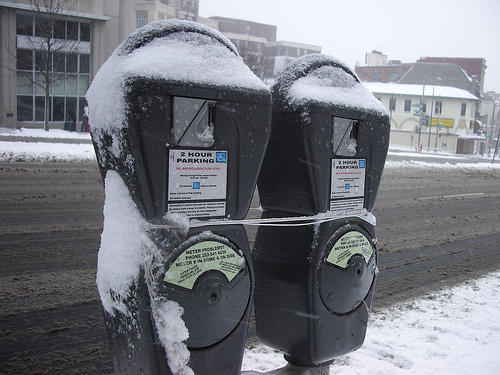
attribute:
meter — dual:
[82, 17, 274, 374]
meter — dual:
[252, 51, 392, 373]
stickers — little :
[163, 145, 371, 219]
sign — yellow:
[424, 114, 454, 128]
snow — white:
[401, 317, 488, 372]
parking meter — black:
[82, 15, 273, 373]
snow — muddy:
[398, 311, 491, 368]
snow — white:
[122, 37, 254, 90]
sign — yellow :
[429, 118, 456, 128]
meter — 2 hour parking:
[71, 10, 393, 374]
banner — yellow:
[411, 99, 481, 146]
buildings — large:
[2, 0, 496, 150]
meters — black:
[78, 9, 401, 374]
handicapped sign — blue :
[209, 149, 234, 171]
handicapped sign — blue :
[348, 149, 368, 176]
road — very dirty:
[1, 156, 499, 369]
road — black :
[372, 160, 478, 294]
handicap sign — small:
[213, 148, 230, 166]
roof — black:
[350, 56, 484, 88]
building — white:
[354, 78, 484, 166]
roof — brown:
[359, 57, 489, 95]